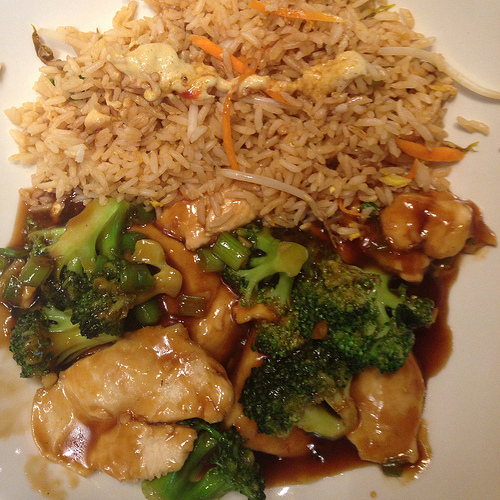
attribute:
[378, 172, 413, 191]
egg — small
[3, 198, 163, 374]
broccoli pieces — in the sauce, green, steamed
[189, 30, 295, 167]
carrots — small, orange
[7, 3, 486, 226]
rice — white, fried, tan colored, off white color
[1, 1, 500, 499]
plate — white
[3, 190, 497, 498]
sauce — brown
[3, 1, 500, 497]
food — a chinese dish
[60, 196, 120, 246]
stem of broccoli — green